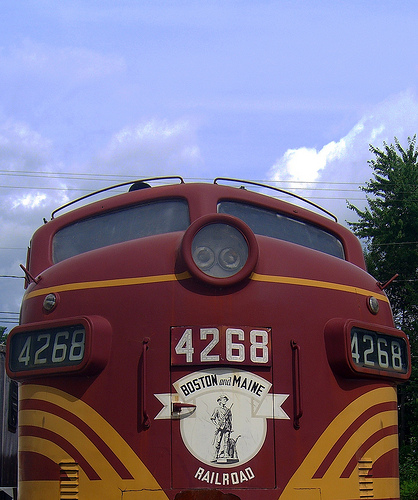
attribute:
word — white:
[187, 465, 255, 490]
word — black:
[179, 369, 218, 397]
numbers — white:
[171, 327, 270, 367]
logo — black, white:
[147, 367, 293, 487]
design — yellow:
[273, 385, 404, 499]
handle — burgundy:
[375, 269, 399, 298]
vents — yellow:
[354, 457, 376, 499]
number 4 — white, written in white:
[14, 334, 33, 370]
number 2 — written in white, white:
[34, 332, 53, 366]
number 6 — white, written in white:
[51, 328, 69, 366]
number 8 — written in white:
[65, 326, 88, 367]